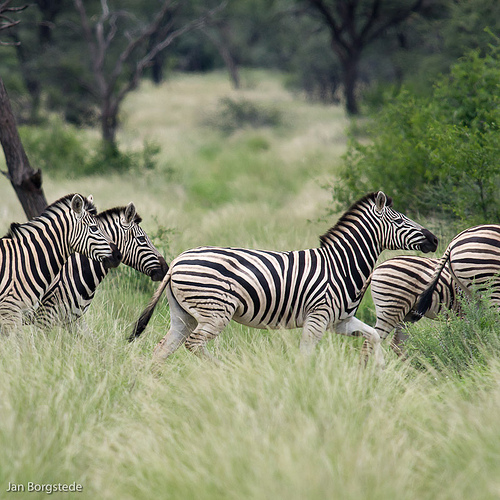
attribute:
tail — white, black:
[411, 239, 493, 343]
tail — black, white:
[95, 278, 171, 350]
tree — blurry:
[75, 67, 138, 177]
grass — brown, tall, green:
[119, 360, 315, 455]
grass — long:
[221, 387, 353, 467]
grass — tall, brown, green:
[9, 75, 494, 485]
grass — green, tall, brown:
[302, 374, 408, 433]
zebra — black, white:
[134, 182, 440, 383]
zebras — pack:
[0, 185, 499, 387]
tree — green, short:
[345, 41, 497, 211]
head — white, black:
[91, 200, 166, 296]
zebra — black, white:
[129, 190, 436, 347]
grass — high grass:
[0, 190, 499, 497]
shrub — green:
[342, 80, 499, 208]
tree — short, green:
[301, 27, 484, 238]